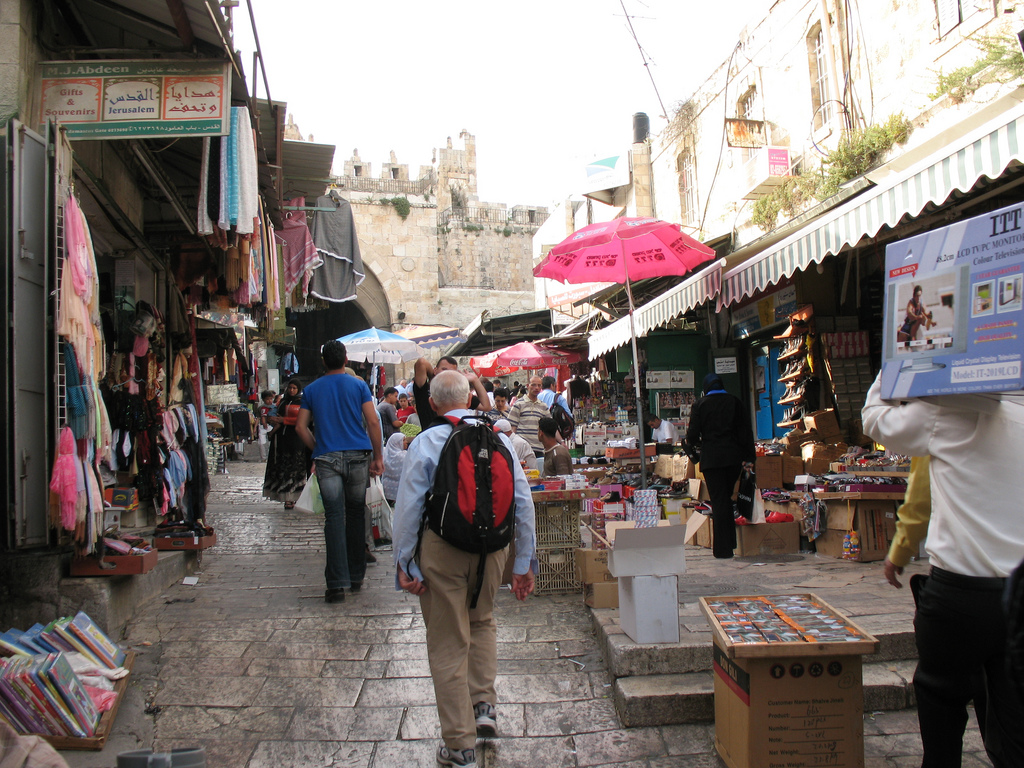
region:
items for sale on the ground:
[1, 503, 129, 767]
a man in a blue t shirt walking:
[286, 345, 373, 583]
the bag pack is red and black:
[432, 420, 515, 566]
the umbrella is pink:
[545, 218, 724, 336]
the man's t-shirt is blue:
[301, 376, 374, 472]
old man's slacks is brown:
[403, 528, 537, 748]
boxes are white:
[595, 518, 703, 651]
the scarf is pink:
[46, 429, 82, 527]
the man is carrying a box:
[852, 229, 1018, 458]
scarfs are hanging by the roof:
[192, 106, 297, 255]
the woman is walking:
[257, 369, 309, 553]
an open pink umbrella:
[527, 212, 723, 289]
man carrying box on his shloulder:
[860, 196, 1019, 757]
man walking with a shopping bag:
[296, 336, 399, 606]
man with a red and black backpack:
[389, 359, 538, 765]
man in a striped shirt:
[503, 373, 555, 454]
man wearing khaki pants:
[392, 356, 539, 761]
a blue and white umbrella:
[329, 321, 422, 370]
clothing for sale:
[50, 175, 114, 571]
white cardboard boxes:
[600, 513, 715, 644]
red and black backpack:
[432, 403, 525, 566]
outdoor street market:
[78, 103, 955, 749]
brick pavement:
[228, 569, 317, 759]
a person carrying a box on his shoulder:
[862, 220, 1017, 752]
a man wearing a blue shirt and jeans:
[293, 333, 391, 615]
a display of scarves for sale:
[50, 181, 127, 564]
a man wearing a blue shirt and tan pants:
[385, 368, 529, 764]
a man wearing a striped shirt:
[503, 370, 552, 450]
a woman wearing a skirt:
[262, 378, 313, 514]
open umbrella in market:
[546, 207, 718, 408]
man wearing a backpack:
[406, 360, 549, 766]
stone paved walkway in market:
[189, 553, 344, 766]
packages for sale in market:
[12, 595, 145, 754]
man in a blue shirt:
[294, 328, 387, 562]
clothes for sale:
[94, 282, 230, 545]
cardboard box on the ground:
[700, 617, 888, 757]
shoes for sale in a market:
[764, 313, 841, 441]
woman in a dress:
[267, 383, 326, 495]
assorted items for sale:
[564, 348, 695, 484]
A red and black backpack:
[431, 388, 555, 592]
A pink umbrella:
[526, 180, 717, 443]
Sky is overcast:
[361, 4, 612, 124]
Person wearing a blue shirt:
[265, 351, 397, 538]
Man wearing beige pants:
[388, 365, 522, 760]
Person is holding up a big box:
[825, 199, 1012, 630]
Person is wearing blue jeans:
[288, 312, 410, 641]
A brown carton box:
[686, 595, 879, 752]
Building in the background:
[304, 108, 563, 324]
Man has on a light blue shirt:
[366, 369, 559, 616]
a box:
[879, 238, 1016, 391]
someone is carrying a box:
[892, 225, 1016, 748]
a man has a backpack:
[409, 368, 527, 765]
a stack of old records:
[13, 617, 140, 750]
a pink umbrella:
[528, 202, 744, 317]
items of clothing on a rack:
[103, 282, 221, 586]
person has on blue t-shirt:
[300, 352, 383, 469]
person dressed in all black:
[687, 382, 761, 560]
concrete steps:
[567, 608, 707, 732]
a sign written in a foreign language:
[33, 45, 274, 145]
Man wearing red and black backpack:
[382, 347, 579, 672]